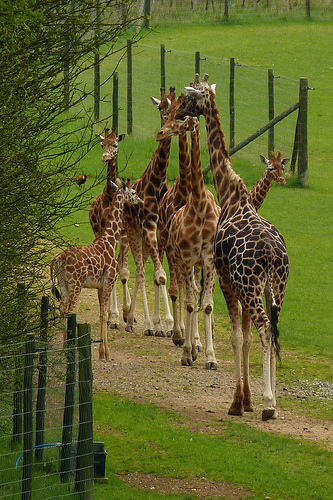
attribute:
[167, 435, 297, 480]
grass — area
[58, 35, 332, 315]
giraffes — group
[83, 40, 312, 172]
fence — part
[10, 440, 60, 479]
hose — blue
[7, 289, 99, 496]
curved fence — wood, wire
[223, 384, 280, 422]
hooves — brown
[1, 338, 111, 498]
fence — area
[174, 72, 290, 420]
giraffe — standing, black, tan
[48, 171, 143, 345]
giraffe — small